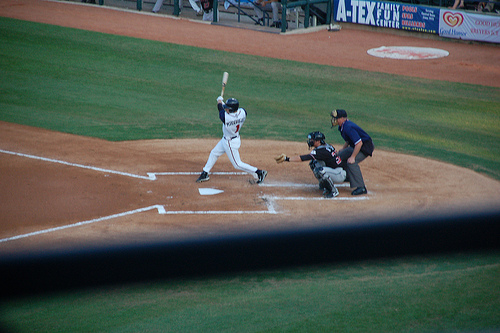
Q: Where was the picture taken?
A: It was taken at the field.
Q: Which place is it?
A: It is a field.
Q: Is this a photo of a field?
A: Yes, it is showing a field.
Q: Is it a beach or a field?
A: It is a field.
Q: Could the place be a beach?
A: No, it is a field.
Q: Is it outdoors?
A: Yes, it is outdoors.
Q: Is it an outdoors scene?
A: Yes, it is outdoors.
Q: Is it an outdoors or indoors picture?
A: It is outdoors.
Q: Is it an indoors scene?
A: No, it is outdoors.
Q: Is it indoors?
A: No, it is outdoors.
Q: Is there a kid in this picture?
A: No, there are no children.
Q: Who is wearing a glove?
A: The catcher is wearing a glove.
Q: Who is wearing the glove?
A: The catcher is wearing a glove.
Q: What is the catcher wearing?
A: The catcher is wearing a glove.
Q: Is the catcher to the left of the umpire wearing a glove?
A: Yes, the catcher is wearing a glove.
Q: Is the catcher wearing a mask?
A: No, the catcher is wearing a glove.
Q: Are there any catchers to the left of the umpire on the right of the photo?
A: Yes, there is a catcher to the left of the umpire.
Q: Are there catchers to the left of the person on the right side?
A: Yes, there is a catcher to the left of the umpire.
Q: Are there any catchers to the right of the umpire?
A: No, the catcher is to the left of the umpire.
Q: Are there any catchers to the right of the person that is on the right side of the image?
A: No, the catcher is to the left of the umpire.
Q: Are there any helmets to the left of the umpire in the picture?
A: No, there is a catcher to the left of the umpire.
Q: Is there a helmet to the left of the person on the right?
A: No, there is a catcher to the left of the umpire.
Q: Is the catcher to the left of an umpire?
A: Yes, the catcher is to the left of an umpire.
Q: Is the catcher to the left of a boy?
A: No, the catcher is to the left of an umpire.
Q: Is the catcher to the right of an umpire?
A: No, the catcher is to the left of an umpire.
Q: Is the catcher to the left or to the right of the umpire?
A: The catcher is to the left of the umpire.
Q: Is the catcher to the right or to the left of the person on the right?
A: The catcher is to the left of the umpire.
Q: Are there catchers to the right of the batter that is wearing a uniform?
A: Yes, there is a catcher to the right of the batter.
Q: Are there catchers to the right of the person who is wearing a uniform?
A: Yes, there is a catcher to the right of the batter.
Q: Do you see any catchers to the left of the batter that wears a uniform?
A: No, the catcher is to the right of the batter.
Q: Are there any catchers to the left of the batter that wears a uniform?
A: No, the catcher is to the right of the batter.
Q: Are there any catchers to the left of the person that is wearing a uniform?
A: No, the catcher is to the right of the batter.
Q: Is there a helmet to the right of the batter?
A: No, there is a catcher to the right of the batter.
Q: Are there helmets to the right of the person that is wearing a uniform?
A: No, there is a catcher to the right of the batter.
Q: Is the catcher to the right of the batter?
A: Yes, the catcher is to the right of the batter.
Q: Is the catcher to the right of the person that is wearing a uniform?
A: Yes, the catcher is to the right of the batter.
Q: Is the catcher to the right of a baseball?
A: No, the catcher is to the right of the batter.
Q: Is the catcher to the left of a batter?
A: No, the catcher is to the right of a batter.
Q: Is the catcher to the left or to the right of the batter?
A: The catcher is to the right of the batter.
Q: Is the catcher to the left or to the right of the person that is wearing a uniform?
A: The catcher is to the right of the batter.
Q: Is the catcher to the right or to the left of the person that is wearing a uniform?
A: The catcher is to the right of the batter.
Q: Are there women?
A: No, there are no women.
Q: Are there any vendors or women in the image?
A: No, there are no women or vendors.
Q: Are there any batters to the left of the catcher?
A: Yes, there is a batter to the left of the catcher.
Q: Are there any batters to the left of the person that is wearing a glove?
A: Yes, there is a batter to the left of the catcher.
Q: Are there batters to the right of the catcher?
A: No, the batter is to the left of the catcher.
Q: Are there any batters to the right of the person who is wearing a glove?
A: No, the batter is to the left of the catcher.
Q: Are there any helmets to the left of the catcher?
A: No, there is a batter to the left of the catcher.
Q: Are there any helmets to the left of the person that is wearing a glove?
A: No, there is a batter to the left of the catcher.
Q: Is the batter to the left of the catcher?
A: Yes, the batter is to the left of the catcher.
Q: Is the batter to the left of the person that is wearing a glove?
A: Yes, the batter is to the left of the catcher.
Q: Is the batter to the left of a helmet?
A: No, the batter is to the left of the catcher.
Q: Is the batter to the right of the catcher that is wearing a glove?
A: No, the batter is to the left of the catcher.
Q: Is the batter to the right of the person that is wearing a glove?
A: No, the batter is to the left of the catcher.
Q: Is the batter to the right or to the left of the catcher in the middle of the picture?
A: The batter is to the left of the catcher.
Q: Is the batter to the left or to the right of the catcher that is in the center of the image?
A: The batter is to the left of the catcher.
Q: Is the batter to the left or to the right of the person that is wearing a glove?
A: The batter is to the left of the catcher.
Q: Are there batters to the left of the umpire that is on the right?
A: Yes, there is a batter to the left of the umpire.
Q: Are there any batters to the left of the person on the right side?
A: Yes, there is a batter to the left of the umpire.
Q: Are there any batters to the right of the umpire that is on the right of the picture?
A: No, the batter is to the left of the umpire.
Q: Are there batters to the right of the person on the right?
A: No, the batter is to the left of the umpire.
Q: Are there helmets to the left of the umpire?
A: No, there is a batter to the left of the umpire.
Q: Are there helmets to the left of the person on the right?
A: No, there is a batter to the left of the umpire.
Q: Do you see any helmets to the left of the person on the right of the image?
A: No, there is a batter to the left of the umpire.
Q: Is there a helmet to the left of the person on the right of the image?
A: No, there is a batter to the left of the umpire.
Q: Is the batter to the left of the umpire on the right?
A: Yes, the batter is to the left of the umpire.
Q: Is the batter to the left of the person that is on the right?
A: Yes, the batter is to the left of the umpire.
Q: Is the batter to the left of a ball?
A: No, the batter is to the left of the umpire.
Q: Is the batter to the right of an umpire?
A: No, the batter is to the left of an umpire.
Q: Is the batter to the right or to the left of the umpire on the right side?
A: The batter is to the left of the umpire.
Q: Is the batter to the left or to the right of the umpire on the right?
A: The batter is to the left of the umpire.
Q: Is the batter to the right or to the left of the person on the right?
A: The batter is to the left of the umpire.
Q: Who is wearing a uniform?
A: The batter is wearing a uniform.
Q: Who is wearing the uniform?
A: The batter is wearing a uniform.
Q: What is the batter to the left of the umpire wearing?
A: The batter is wearing a uniform.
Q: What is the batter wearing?
A: The batter is wearing a uniform.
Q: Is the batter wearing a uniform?
A: Yes, the batter is wearing a uniform.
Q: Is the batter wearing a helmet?
A: No, the batter is wearing a uniform.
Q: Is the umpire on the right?
A: Yes, the umpire is on the right of the image.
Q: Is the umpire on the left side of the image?
A: No, the umpire is on the right of the image.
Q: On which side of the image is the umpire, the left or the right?
A: The umpire is on the right of the image.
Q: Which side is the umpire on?
A: The umpire is on the right of the image.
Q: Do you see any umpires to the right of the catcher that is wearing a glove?
A: Yes, there is an umpire to the right of the catcher.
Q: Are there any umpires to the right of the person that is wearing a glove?
A: Yes, there is an umpire to the right of the catcher.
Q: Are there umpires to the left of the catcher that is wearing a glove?
A: No, the umpire is to the right of the catcher.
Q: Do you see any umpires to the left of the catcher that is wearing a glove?
A: No, the umpire is to the right of the catcher.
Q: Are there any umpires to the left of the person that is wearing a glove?
A: No, the umpire is to the right of the catcher.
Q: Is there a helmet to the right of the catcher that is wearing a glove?
A: No, there is an umpire to the right of the catcher.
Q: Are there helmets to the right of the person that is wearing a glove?
A: No, there is an umpire to the right of the catcher.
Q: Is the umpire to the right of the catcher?
A: Yes, the umpire is to the right of the catcher.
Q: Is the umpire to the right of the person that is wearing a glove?
A: Yes, the umpire is to the right of the catcher.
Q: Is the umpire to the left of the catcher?
A: No, the umpire is to the right of the catcher.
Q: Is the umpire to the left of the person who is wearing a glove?
A: No, the umpire is to the right of the catcher.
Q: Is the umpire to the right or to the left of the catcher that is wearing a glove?
A: The umpire is to the right of the catcher.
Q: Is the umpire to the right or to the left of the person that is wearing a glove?
A: The umpire is to the right of the catcher.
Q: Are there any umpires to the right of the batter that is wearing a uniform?
A: Yes, there is an umpire to the right of the batter.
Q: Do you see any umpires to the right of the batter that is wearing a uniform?
A: Yes, there is an umpire to the right of the batter.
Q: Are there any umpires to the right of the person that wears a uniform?
A: Yes, there is an umpire to the right of the batter.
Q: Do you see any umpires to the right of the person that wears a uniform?
A: Yes, there is an umpire to the right of the batter.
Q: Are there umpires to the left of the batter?
A: No, the umpire is to the right of the batter.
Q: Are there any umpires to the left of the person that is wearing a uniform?
A: No, the umpire is to the right of the batter.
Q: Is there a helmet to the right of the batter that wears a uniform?
A: No, there is an umpire to the right of the batter.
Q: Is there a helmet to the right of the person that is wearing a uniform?
A: No, there is an umpire to the right of the batter.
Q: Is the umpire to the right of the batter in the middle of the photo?
A: Yes, the umpire is to the right of the batter.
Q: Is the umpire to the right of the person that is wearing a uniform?
A: Yes, the umpire is to the right of the batter.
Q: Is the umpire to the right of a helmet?
A: No, the umpire is to the right of the batter.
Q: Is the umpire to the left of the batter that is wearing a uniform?
A: No, the umpire is to the right of the batter.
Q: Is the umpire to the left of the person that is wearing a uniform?
A: No, the umpire is to the right of the batter.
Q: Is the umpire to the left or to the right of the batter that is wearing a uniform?
A: The umpire is to the right of the batter.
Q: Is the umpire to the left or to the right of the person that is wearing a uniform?
A: The umpire is to the right of the batter.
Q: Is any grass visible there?
A: Yes, there is grass.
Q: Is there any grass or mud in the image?
A: Yes, there is grass.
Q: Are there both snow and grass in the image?
A: No, there is grass but no snow.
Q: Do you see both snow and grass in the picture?
A: No, there is grass but no snow.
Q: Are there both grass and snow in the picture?
A: No, there is grass but no snow.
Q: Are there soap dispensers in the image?
A: No, there are no soap dispensers.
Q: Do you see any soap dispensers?
A: No, there are no soap dispensers.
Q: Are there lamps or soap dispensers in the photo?
A: No, there are no soap dispensers or lamps.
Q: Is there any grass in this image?
A: Yes, there is grass.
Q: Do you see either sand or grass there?
A: Yes, there is grass.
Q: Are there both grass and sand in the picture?
A: No, there is grass but no sand.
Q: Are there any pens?
A: No, there are no pens.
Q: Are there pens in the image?
A: No, there are no pens.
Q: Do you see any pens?
A: No, there are no pens.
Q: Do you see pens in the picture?
A: No, there are no pens.